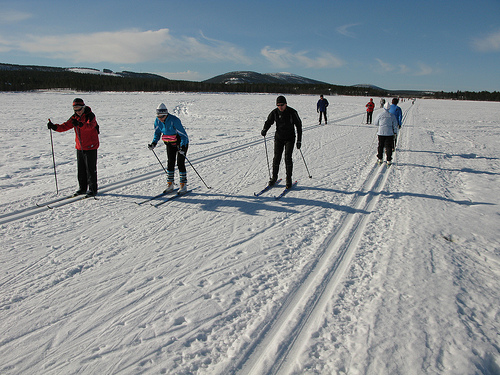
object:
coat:
[49, 107, 101, 152]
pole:
[297, 144, 315, 180]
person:
[46, 97, 100, 199]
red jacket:
[363, 101, 375, 113]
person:
[363, 98, 377, 123]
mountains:
[196, 71, 422, 98]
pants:
[164, 140, 188, 182]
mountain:
[0, 63, 201, 93]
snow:
[0, 88, 498, 374]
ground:
[0, 89, 499, 374]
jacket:
[373, 109, 399, 137]